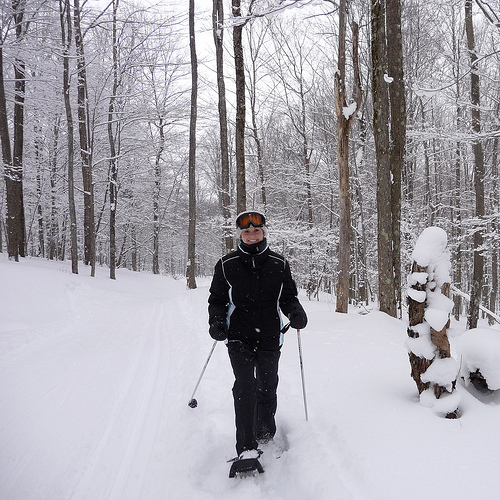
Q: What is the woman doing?
A: Skiing.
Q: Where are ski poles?
A: In woman's hands.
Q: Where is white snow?
A: On tree branches.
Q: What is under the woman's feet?
A: Skis.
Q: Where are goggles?
A: On woman's head.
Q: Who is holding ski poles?
A: Skier.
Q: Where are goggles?
A: On skier's head.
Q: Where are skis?
A: Under skiers feet.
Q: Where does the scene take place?
A: On a ski slope.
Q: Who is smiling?
A: The skier.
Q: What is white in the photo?
A: Snow.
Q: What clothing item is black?
A: Snow pants.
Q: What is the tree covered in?
A: Snow.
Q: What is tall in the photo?
A: Trees.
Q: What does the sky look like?
A: Cloudy.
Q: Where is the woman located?
A: In snow.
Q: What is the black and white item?
A: Snow jacket.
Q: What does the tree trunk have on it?
A: Snow.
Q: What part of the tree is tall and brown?
A: Trunk.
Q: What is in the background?
A: Trees.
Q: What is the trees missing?
A: Leaves.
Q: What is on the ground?
A: Snow.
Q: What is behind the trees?
A: The sky.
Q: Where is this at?
A: Slope.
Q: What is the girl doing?
A: Skiing.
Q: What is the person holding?
A: Ski poles.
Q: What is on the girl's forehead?
A: Goggles.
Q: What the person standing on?
A: Skis.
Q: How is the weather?
A: Cold.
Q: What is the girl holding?
A: Ski poles.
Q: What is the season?
A: Winter.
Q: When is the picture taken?
A: Daytime.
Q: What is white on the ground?
A: Snow.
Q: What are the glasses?
A: Goggles.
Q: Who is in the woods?
A: A girl.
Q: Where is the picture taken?
A: In a park.